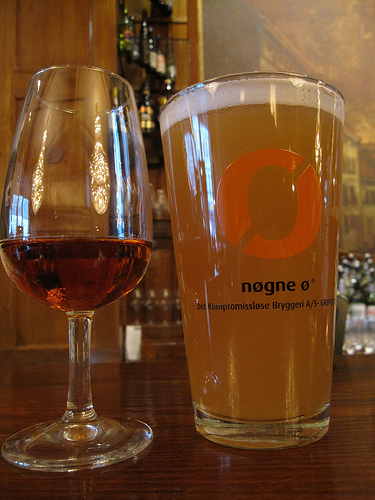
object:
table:
[0, 352, 375, 498]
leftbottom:
[0, 309, 155, 473]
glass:
[0, 63, 153, 478]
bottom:
[1, 417, 154, 472]